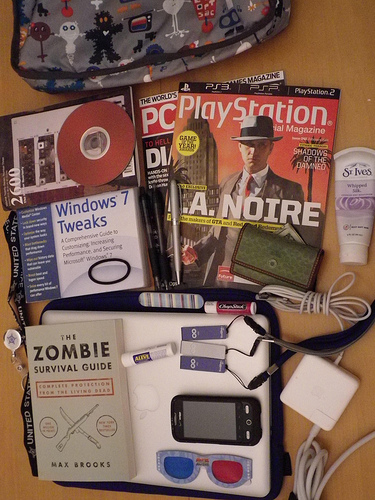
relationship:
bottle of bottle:
[332, 145, 374, 266] [332, 145, 374, 266]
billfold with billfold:
[229, 222, 325, 295] [229, 222, 325, 295]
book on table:
[23, 319, 137, 483] [2, 15, 364, 497]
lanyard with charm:
[0, 216, 52, 459] [1, 316, 55, 355]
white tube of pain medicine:
[120, 343, 178, 368] [124, 351, 168, 357]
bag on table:
[4, 3, 324, 105] [2, 15, 364, 497]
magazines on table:
[128, 71, 370, 312] [2, 15, 364, 497]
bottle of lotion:
[330, 148, 372, 265] [340, 171, 369, 232]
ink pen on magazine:
[165, 175, 186, 286] [161, 78, 341, 294]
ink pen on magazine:
[165, 175, 186, 286] [138, 65, 288, 293]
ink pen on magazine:
[135, 183, 162, 291] [138, 65, 288, 293]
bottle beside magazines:
[332, 145, 374, 266] [139, 87, 341, 291]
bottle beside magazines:
[332, 145, 374, 266] [0, 88, 145, 186]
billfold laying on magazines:
[224, 218, 326, 296] [162, 74, 346, 296]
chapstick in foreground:
[204, 300, 255, 315] [1, 2, 371, 499]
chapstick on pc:
[204, 300, 255, 315] [36, 308, 273, 497]